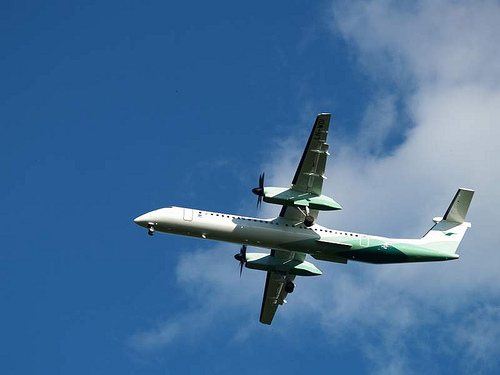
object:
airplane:
[132, 113, 477, 326]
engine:
[261, 186, 345, 211]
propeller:
[252, 172, 267, 207]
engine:
[244, 253, 323, 277]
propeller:
[234, 244, 250, 278]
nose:
[132, 208, 164, 235]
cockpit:
[159, 204, 177, 212]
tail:
[417, 186, 476, 254]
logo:
[436, 229, 461, 238]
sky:
[2, 3, 499, 372]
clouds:
[123, 1, 500, 372]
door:
[182, 207, 194, 222]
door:
[358, 234, 371, 247]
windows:
[253, 216, 261, 224]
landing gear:
[147, 207, 315, 291]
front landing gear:
[146, 222, 156, 236]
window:
[165, 205, 175, 209]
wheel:
[302, 216, 315, 227]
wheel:
[284, 282, 295, 292]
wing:
[258, 249, 307, 325]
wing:
[276, 111, 332, 224]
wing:
[440, 187, 475, 225]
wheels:
[147, 215, 165, 240]